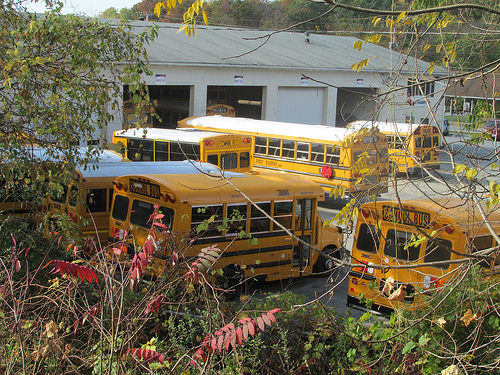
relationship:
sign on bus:
[318, 161, 333, 183] [173, 112, 387, 212]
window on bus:
[291, 138, 314, 163] [173, 112, 387, 212]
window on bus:
[253, 137, 267, 154] [173, 112, 387, 212]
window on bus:
[265, 136, 280, 161] [173, 112, 387, 212]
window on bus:
[308, 143, 327, 166] [173, 112, 387, 212]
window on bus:
[422, 233, 456, 270] [346, 197, 498, 322]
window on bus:
[355, 220, 385, 252] [346, 197, 498, 322]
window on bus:
[385, 225, 424, 265] [346, 197, 498, 322]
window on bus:
[468, 234, 493, 274] [346, 197, 498, 322]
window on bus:
[274, 198, 292, 228] [109, 175, 347, 292]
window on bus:
[185, 206, 222, 238] [109, 175, 347, 292]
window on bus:
[225, 205, 249, 235] [109, 175, 347, 292]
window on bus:
[245, 203, 274, 233] [109, 175, 347, 292]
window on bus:
[310, 140, 323, 163] [179, 110, 390, 201]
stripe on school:
[131, 181, 144, 187] [45, 15, 499, 321]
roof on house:
[452, 68, 497, 103] [445, 64, 498, 136]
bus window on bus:
[357, 217, 381, 259] [346, 197, 498, 322]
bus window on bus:
[424, 232, 456, 272] [346, 197, 498, 322]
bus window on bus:
[189, 201, 226, 239] [109, 175, 347, 292]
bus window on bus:
[271, 197, 295, 231] [109, 175, 347, 292]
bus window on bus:
[110, 193, 135, 220] [109, 175, 347, 292]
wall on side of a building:
[249, 70, 282, 85] [7, 9, 446, 167]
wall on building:
[181, 85, 221, 123] [2, 7, 470, 176]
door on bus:
[290, 197, 315, 270] [144, 175, 327, 272]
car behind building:
[444, 111, 453, 145] [4, 20, 451, 155]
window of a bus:
[355, 220, 381, 254] [110, 171, 342, 281]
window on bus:
[253, 127, 290, 159] [346, 197, 498, 322]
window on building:
[400, 80, 430, 98] [14, 7, 444, 182]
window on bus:
[323, 139, 340, 165] [179, 110, 390, 201]